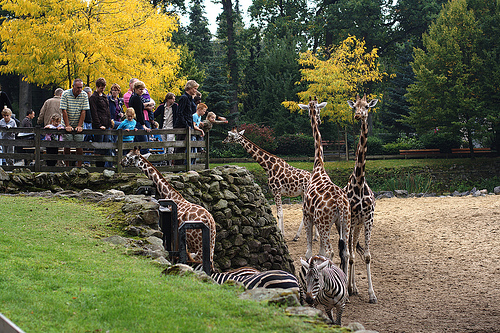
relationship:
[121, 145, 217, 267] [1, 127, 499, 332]
giraffe in a zoo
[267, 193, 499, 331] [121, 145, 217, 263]
dirt under giraffe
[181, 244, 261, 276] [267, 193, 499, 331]
giraffe laying on dirt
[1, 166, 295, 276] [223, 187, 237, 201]
wall made of stone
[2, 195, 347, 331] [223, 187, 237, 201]
grass above stone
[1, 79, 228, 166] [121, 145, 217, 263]
people above giraffe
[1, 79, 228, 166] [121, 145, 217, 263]
people watching giraffe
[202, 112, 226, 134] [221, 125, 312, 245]
girl reaching for giraffe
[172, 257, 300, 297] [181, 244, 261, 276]
zebra near giraffe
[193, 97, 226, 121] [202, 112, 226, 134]
man near girl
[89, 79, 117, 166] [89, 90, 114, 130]
man in a black shirt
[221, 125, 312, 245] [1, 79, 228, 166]
giraffe near people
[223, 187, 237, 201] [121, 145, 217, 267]
stone near giraffe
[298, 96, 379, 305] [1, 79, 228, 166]
giraffes looking away from people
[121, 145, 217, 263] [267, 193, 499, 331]
giraffe on top of dirt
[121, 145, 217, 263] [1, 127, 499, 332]
giraffe in zoo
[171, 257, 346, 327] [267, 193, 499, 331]
zebras on top of dirt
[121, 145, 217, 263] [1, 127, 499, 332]
giraffe in a zoo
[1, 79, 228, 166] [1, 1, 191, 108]
people in front of trees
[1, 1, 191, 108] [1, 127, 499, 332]
trees in a zoo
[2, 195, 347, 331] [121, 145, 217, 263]
grass near giraffe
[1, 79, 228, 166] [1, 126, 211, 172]
people leaning on a fence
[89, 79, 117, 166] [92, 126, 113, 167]
man with jeans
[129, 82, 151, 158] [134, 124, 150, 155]
man with jeans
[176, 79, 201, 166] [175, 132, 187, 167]
man with jeans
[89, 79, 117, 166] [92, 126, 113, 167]
man wearing jeans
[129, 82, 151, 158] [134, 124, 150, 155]
man wearing jeans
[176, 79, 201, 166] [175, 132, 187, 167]
man wearing jeans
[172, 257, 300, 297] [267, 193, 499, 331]
zebra on top of dirt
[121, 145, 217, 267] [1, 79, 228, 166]
giraffe watching people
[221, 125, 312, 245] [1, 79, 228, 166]
giraffe watching people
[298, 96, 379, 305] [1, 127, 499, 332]
giraffes in a zoo